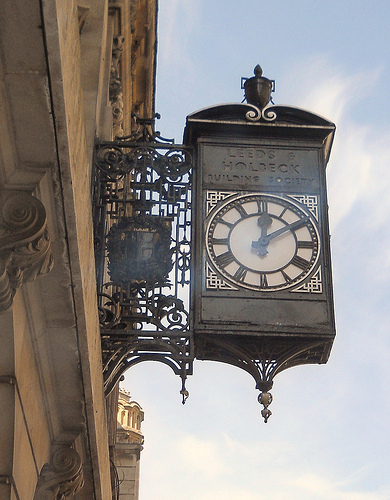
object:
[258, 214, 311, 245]
clock hand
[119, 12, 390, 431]
clouds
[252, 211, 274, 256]
black hands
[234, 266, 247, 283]
roman numerals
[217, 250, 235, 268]
roman numerals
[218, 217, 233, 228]
roman numerals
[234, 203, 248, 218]
roman numerals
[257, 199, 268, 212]
black numbers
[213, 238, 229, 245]
number nine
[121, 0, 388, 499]
sky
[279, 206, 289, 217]
number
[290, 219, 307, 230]
number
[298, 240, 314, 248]
number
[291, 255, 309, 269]
number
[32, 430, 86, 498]
design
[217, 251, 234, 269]
roman numeral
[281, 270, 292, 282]
numeral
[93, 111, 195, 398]
iron bracket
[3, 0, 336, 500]
building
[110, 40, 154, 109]
window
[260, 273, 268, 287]
numerals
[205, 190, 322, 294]
face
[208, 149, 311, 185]
words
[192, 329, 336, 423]
bottom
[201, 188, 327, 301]
design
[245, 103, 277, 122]
design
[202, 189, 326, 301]
clock